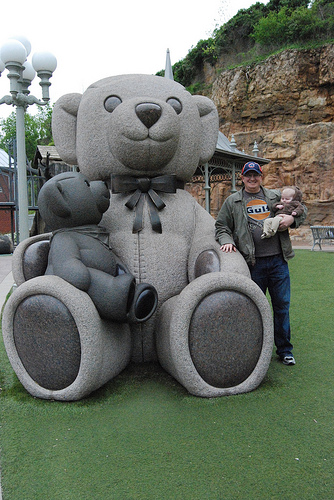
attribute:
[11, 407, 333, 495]
grass — green, manicured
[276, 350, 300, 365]
sneakers — silver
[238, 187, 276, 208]
bow — shiny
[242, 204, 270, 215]
word — blue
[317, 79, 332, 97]
spot — black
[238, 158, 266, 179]
cap — orange, blue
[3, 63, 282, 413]
bear — enormous, giant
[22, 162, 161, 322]
bear — gray, black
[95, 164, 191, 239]
bow tie — large, black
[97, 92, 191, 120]
eyes — round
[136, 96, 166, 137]
nose — triangular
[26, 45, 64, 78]
bulb — round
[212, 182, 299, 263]
jacket — brown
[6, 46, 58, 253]
post — tall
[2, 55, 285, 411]
teddy bear — gigantic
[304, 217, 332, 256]
bench — here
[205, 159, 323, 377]
dad — smiling